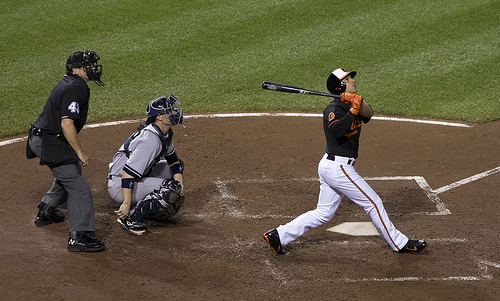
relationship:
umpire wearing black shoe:
[18, 40, 115, 267] [66, 233, 107, 258]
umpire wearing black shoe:
[18, 40, 115, 267] [30, 207, 67, 226]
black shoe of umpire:
[68, 232, 108, 253] [24, 46, 108, 254]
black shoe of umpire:
[34, 197, 67, 224] [24, 46, 108, 254]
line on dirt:
[212, 172, 427, 185] [183, 124, 318, 211]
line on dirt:
[413, 174, 452, 216] [183, 124, 318, 211]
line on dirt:
[231, 209, 450, 221] [183, 124, 318, 211]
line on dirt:
[212, 177, 242, 218] [183, 124, 318, 211]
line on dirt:
[431, 165, 499, 195] [183, 124, 318, 211]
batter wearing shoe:
[260, 67, 429, 256] [404, 237, 426, 255]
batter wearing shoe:
[260, 67, 429, 256] [261, 227, 285, 262]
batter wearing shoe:
[260, 67, 429, 256] [256, 227, 289, 255]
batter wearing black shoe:
[260, 67, 429, 256] [395, 237, 429, 253]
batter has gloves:
[271, 60, 438, 268] [337, 90, 364, 122]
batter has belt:
[260, 67, 429, 256] [317, 147, 364, 167]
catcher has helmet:
[104, 91, 204, 233] [140, 93, 177, 122]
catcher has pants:
[104, 94, 188, 237] [107, 160, 176, 203]